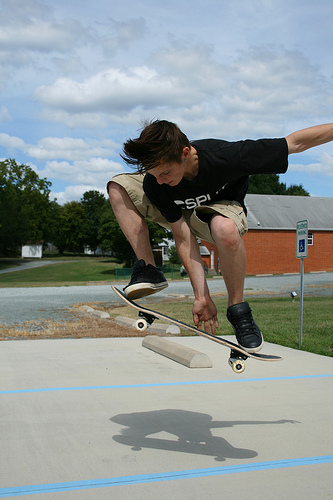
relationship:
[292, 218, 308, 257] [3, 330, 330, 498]
sign next to parking lot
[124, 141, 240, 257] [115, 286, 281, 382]
boy riding skateboard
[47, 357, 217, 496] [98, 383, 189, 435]
blue stripe painted on concrete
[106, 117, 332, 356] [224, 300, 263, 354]
boy has feet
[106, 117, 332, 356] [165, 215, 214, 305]
boy has arm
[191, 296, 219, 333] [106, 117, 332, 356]
hand of boy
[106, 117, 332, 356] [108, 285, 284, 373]
boy on skateboard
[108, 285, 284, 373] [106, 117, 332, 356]
skateboard under boy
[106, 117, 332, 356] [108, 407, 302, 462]
boy has shadow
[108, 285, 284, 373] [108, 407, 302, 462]
skateboard has shadow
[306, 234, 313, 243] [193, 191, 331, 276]
window on building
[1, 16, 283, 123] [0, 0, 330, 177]
cloud in sky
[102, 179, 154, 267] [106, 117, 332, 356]
leg on boy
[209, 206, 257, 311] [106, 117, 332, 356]
leg on boy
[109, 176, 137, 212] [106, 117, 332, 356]
knee on boy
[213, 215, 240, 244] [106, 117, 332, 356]
knee on boy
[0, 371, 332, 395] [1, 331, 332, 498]
blue stripe on concrete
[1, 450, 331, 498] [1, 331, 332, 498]
stripe on concrete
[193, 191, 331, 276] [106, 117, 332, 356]
building behind boy